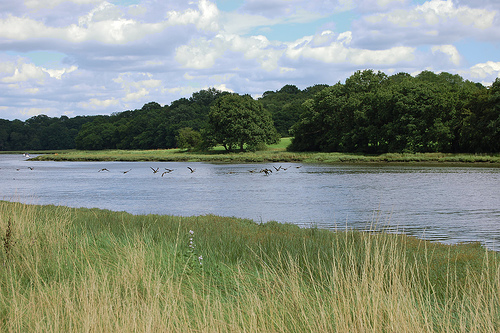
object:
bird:
[271, 165, 282, 172]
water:
[347, 164, 497, 218]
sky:
[0, 0, 496, 143]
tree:
[202, 82, 276, 156]